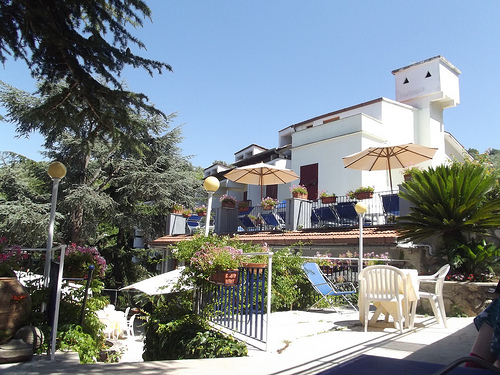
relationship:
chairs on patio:
[352, 268, 449, 340] [226, 271, 444, 355]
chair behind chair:
[298, 248, 360, 308] [359, 265, 403, 318]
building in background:
[266, 43, 454, 206] [34, 4, 461, 220]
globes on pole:
[355, 198, 369, 213] [353, 215, 366, 276]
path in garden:
[2, 344, 245, 374] [7, 252, 492, 355]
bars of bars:
[200, 271, 265, 335] [199, 267, 266, 349]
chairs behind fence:
[216, 198, 294, 241] [236, 190, 396, 230]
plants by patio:
[187, 218, 310, 321] [226, 271, 444, 355]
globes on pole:
[355, 198, 369, 213] [348, 214, 370, 275]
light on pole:
[208, 175, 224, 197] [203, 193, 218, 232]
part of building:
[383, 43, 462, 96] [266, 43, 454, 206]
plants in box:
[187, 218, 310, 321] [209, 267, 267, 293]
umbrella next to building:
[237, 156, 296, 189] [266, 43, 454, 206]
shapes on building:
[401, 71, 435, 88] [266, 43, 454, 206]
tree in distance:
[25, 8, 150, 131] [10, 7, 171, 301]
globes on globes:
[355, 194, 376, 213] [355, 198, 369, 213]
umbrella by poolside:
[325, 127, 439, 184] [133, 149, 413, 333]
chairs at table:
[352, 268, 449, 340] [345, 245, 406, 284]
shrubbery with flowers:
[178, 236, 317, 300] [193, 232, 239, 262]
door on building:
[300, 165, 319, 210] [275, 55, 495, 229]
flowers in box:
[193, 232, 239, 262] [209, 267, 267, 293]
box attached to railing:
[209, 267, 267, 293] [188, 264, 355, 312]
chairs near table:
[352, 268, 449, 340] [345, 245, 406, 284]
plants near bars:
[187, 218, 310, 321] [199, 267, 266, 349]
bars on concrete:
[199, 267, 266, 349] [210, 286, 451, 363]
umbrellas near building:
[225, 156, 405, 171] [266, 43, 454, 206]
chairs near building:
[216, 198, 294, 241] [266, 43, 454, 206]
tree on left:
[25, 8, 150, 131] [5, 7, 124, 261]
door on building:
[300, 165, 319, 210] [266, 43, 454, 206]